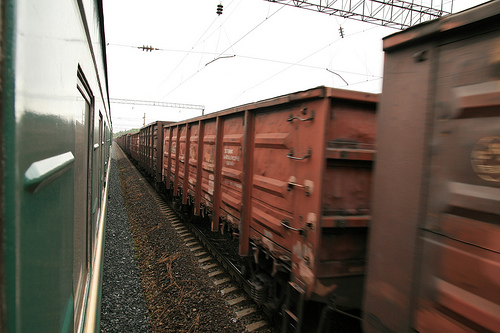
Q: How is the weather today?
A: It is clear.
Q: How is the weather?
A: It is clear.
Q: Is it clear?
A: Yes, it is clear.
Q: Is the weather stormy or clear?
A: It is clear.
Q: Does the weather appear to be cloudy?
A: No, it is clear.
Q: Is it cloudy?
A: No, it is clear.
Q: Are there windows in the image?
A: Yes, there is a window.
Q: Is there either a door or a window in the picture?
A: Yes, there is a window.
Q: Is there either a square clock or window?
A: Yes, there is a square window.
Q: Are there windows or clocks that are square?
A: Yes, the window is square.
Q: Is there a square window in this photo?
A: Yes, there is a square window.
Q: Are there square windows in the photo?
A: Yes, there is a square window.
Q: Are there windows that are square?
A: Yes, there is a window that is square.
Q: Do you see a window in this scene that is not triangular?
A: Yes, there is a square window.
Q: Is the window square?
A: Yes, the window is square.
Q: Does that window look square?
A: Yes, the window is square.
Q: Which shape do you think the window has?
A: The window has square shape.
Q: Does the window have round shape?
A: No, the window is square.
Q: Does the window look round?
A: No, the window is square.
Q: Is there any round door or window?
A: No, there is a window but it is square.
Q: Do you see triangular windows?
A: No, there is a window but it is square.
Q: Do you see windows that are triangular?
A: No, there is a window but it is square.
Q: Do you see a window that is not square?
A: No, there is a window but it is square.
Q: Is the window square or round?
A: The window is square.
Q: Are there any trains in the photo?
A: Yes, there is a train.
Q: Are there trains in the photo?
A: Yes, there is a train.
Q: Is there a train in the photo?
A: Yes, there is a train.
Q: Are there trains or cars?
A: Yes, there is a train.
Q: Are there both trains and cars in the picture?
A: Yes, there are both a train and a car.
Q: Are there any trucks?
A: No, there are no trucks.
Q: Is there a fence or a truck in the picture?
A: No, there are no trucks or fences.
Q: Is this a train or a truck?
A: This is a train.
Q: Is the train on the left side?
A: Yes, the train is on the left of the image.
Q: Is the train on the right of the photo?
A: No, the train is on the left of the image.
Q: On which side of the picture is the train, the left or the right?
A: The train is on the left of the image.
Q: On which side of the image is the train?
A: The train is on the left of the image.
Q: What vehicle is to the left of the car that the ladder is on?
A: The vehicle is a train.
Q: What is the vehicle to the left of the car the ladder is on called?
A: The vehicle is a train.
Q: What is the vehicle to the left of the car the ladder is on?
A: The vehicle is a train.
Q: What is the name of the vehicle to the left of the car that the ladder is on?
A: The vehicle is a train.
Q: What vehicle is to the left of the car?
A: The vehicle is a train.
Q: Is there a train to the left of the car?
A: Yes, there is a train to the left of the car.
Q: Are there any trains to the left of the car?
A: Yes, there is a train to the left of the car.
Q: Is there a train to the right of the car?
A: No, the train is to the left of the car.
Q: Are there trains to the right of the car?
A: No, the train is to the left of the car.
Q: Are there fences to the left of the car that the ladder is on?
A: No, there is a train to the left of the car.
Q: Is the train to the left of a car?
A: Yes, the train is to the left of a car.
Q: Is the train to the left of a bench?
A: No, the train is to the left of a car.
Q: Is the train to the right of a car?
A: No, the train is to the left of a car.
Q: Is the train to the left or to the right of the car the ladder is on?
A: The train is to the left of the car.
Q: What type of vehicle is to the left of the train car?
A: The vehicle is a train.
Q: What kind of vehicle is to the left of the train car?
A: The vehicle is a train.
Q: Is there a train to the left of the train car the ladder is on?
A: Yes, there is a train to the left of the train car.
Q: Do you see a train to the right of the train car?
A: No, the train is to the left of the train car.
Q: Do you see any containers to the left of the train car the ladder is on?
A: No, there is a train to the left of the train car.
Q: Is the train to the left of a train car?
A: Yes, the train is to the left of a train car.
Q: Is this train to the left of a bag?
A: No, the train is to the left of a train car.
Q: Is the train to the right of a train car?
A: No, the train is to the left of a train car.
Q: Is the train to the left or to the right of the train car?
A: The train is to the left of the train car.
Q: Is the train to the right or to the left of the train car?
A: The train is to the left of the train car.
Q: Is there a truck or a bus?
A: No, there are no trucks or buses.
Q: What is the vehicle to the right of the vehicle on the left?
A: The vehicle is a car.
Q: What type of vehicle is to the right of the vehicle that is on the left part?
A: The vehicle is a car.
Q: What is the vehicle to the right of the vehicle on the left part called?
A: The vehicle is a car.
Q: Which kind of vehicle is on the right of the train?
A: The vehicle is a car.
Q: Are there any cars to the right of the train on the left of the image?
A: Yes, there is a car to the right of the train.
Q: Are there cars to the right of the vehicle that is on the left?
A: Yes, there is a car to the right of the train.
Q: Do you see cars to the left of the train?
A: No, the car is to the right of the train.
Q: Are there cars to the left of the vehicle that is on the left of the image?
A: No, the car is to the right of the train.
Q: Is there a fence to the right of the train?
A: No, there is a car to the right of the train.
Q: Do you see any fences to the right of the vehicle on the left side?
A: No, there is a car to the right of the train.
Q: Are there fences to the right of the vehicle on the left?
A: No, there is a car to the right of the train.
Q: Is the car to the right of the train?
A: Yes, the car is to the right of the train.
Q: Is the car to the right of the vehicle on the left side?
A: Yes, the car is to the right of the train.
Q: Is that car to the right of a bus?
A: No, the car is to the right of the train.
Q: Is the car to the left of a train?
A: No, the car is to the right of a train.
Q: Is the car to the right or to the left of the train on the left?
A: The car is to the right of the train.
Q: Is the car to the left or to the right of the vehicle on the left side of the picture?
A: The car is to the right of the train.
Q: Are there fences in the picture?
A: No, there are no fences.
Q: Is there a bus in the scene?
A: No, there are no buses.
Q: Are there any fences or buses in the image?
A: No, there are no buses or fences.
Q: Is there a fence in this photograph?
A: No, there are no fences.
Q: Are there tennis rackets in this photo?
A: No, there are no tennis rackets.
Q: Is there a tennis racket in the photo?
A: No, there are no rackets.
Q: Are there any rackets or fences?
A: No, there are no rackets or fences.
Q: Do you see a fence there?
A: No, there are no fences.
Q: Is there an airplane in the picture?
A: No, there are no airplanes.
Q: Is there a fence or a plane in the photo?
A: No, there are no airplanes or fences.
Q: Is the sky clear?
A: Yes, the sky is clear.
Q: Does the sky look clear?
A: Yes, the sky is clear.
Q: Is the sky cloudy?
A: No, the sky is clear.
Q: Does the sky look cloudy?
A: No, the sky is clear.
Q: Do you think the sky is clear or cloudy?
A: The sky is clear.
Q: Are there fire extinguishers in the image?
A: No, there are no fire extinguishers.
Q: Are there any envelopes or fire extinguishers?
A: No, there are no fire extinguishers or envelopes.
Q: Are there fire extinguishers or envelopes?
A: No, there are no fire extinguishers or envelopes.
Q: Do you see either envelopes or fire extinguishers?
A: No, there are no fire extinguishers or envelopes.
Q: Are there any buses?
A: No, there are no buses.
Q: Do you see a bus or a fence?
A: No, there are no buses or fences.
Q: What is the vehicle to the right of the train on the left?
A: The vehicle is a train car.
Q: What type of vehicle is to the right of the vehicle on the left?
A: The vehicle is a train car.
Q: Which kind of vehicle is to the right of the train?
A: The vehicle is a train car.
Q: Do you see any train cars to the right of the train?
A: Yes, there is a train car to the right of the train.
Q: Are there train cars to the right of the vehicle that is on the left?
A: Yes, there is a train car to the right of the train.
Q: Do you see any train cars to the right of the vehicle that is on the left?
A: Yes, there is a train car to the right of the train.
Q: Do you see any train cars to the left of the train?
A: No, the train car is to the right of the train.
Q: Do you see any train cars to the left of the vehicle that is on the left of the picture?
A: No, the train car is to the right of the train.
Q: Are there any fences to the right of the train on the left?
A: No, there is a train car to the right of the train.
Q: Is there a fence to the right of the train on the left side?
A: No, there is a train car to the right of the train.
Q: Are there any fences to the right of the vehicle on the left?
A: No, there is a train car to the right of the train.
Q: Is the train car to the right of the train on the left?
A: Yes, the train car is to the right of the train.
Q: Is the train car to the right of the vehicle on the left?
A: Yes, the train car is to the right of the train.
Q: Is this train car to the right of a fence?
A: No, the train car is to the right of the train.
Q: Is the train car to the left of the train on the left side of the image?
A: No, the train car is to the right of the train.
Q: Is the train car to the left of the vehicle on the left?
A: No, the train car is to the right of the train.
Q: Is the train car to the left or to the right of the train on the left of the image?
A: The train car is to the right of the train.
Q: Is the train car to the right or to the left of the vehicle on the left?
A: The train car is to the right of the train.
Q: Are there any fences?
A: No, there are no fences.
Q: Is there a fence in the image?
A: No, there are no fences.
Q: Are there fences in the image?
A: No, there are no fences.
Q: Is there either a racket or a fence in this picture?
A: No, there are no fences or rackets.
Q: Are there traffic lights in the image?
A: No, there are no traffic lights.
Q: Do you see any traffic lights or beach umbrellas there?
A: No, there are no traffic lights or beach umbrellas.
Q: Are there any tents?
A: No, there are no tents.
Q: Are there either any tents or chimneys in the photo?
A: No, there are no tents or chimneys.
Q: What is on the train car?
A: The ladder is on the train car.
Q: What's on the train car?
A: The ladder is on the train car.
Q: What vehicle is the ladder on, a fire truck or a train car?
A: The ladder is on a train car.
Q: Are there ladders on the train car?
A: Yes, there is a ladder on the train car.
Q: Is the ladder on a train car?
A: Yes, the ladder is on a train car.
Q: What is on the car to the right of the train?
A: The ladder is on the car.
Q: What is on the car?
A: The ladder is on the car.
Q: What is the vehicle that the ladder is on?
A: The vehicle is a car.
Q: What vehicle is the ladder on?
A: The ladder is on the car.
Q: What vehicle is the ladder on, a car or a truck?
A: The ladder is on a car.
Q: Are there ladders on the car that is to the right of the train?
A: Yes, there is a ladder on the car.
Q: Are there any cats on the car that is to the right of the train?
A: No, there is a ladder on the car.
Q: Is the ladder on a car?
A: Yes, the ladder is on a car.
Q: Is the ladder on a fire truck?
A: No, the ladder is on a car.